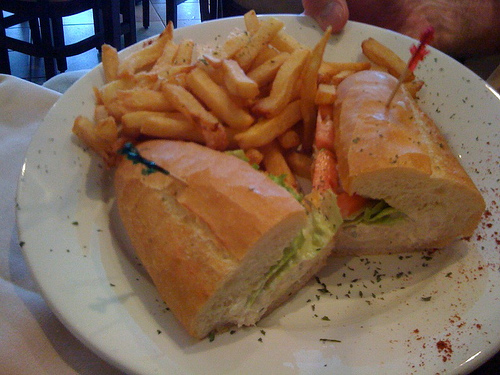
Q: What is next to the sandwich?
A: Fries.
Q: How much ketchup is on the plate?
A: None.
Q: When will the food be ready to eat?
A: It is.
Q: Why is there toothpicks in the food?
A: To hold it together.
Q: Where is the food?
A: On a plate.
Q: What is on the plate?
A: A sandwich and fries.